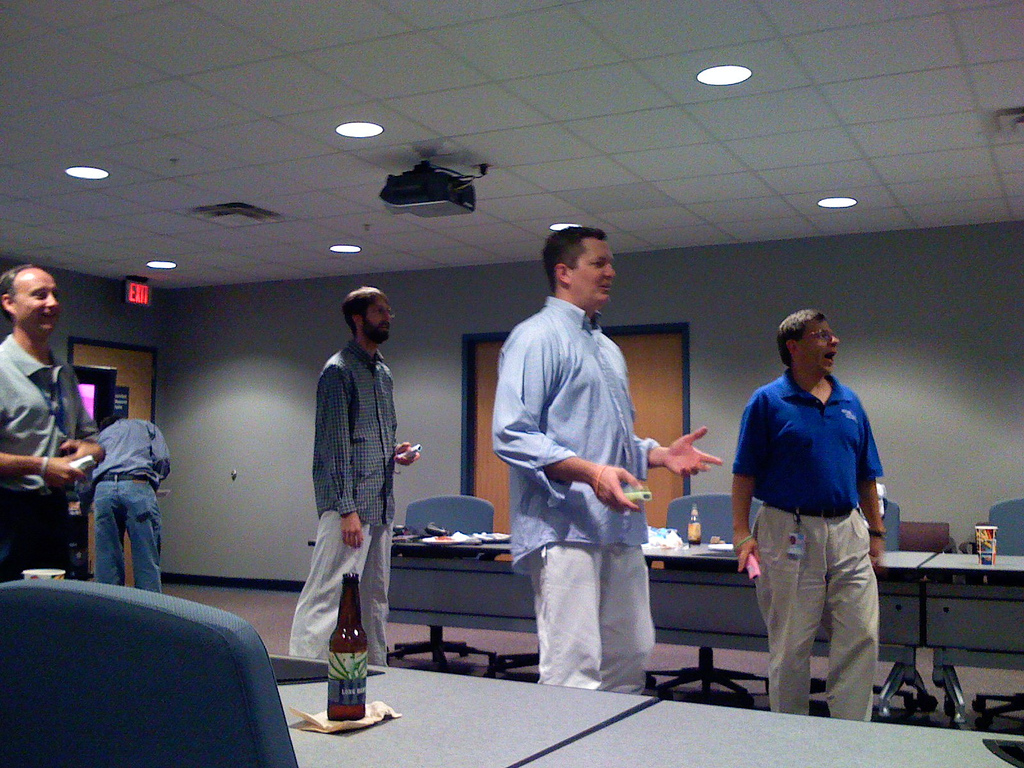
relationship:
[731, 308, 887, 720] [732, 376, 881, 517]
person in shirt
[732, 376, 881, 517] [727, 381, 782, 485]
shirt with sleeve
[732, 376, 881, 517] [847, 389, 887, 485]
shirt with sleeve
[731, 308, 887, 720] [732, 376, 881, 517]
person wearing shirt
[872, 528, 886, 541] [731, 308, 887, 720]
watch on person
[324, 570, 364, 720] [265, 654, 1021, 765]
bottle on table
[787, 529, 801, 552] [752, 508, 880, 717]
tag on pants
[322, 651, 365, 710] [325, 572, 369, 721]
label on bottle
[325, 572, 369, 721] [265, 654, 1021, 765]
bottle on table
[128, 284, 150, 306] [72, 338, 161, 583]
exit sign above door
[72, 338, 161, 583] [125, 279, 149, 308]
door beneath exit sign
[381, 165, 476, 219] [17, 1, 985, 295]
projector device on ceiling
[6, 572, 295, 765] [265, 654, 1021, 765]
chair behind table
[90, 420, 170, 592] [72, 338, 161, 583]
man near door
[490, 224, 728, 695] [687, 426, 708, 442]
man has finger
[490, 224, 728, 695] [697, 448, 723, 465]
man has finger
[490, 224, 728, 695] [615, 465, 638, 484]
man has finger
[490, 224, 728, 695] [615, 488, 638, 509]
man has finger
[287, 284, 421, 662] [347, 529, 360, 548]
person has finger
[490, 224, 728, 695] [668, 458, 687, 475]
man has finger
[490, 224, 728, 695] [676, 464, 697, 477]
man has finger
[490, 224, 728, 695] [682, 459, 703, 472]
man has finger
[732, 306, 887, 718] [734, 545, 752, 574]
person has finger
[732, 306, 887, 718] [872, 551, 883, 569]
person has finger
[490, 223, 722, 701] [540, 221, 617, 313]
man has head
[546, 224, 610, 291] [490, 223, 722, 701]
hair of man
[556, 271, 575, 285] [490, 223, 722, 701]
ear of man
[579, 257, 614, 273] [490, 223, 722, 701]
eye of man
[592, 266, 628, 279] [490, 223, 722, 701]
nose of man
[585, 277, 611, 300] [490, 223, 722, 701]
mouth of man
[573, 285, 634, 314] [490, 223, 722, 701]
chin of man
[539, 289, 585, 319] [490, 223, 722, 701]
neck of man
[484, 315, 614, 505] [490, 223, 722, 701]
arm of man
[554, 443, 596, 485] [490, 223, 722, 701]
wrist of man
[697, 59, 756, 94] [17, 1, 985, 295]
light in ceiling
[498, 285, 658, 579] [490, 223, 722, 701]
shirt of man